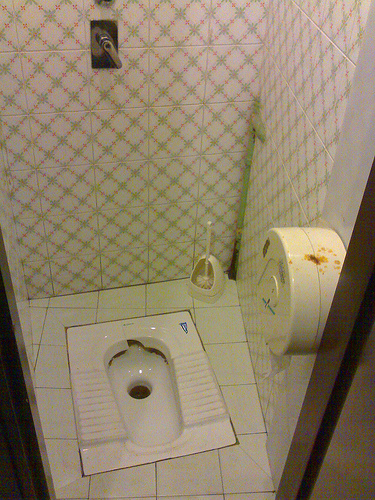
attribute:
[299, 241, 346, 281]
scum — yellow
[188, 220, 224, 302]
cleaner — plastic, for toilet, white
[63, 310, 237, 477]
toilet — ceramic, pit, white, dirty, in floor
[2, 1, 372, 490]
tile — flower design, ceramic, patterned, green, pink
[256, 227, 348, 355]
dispenser — toilet paper dispens, dirty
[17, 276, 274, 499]
tile — white, ceramic, tiled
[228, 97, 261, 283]
pole — brown, green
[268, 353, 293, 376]
paper — small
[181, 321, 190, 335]
symbol — blue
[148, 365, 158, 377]
spot — brown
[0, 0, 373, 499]
bathroom — dirty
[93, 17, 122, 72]
handle — silver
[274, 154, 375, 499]
frame — brown